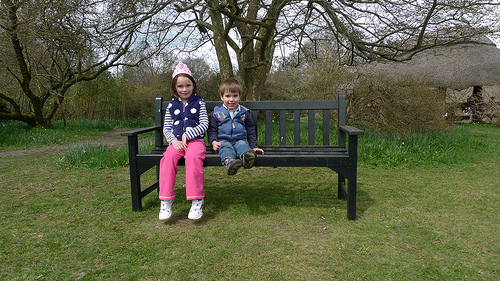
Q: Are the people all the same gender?
A: No, they are both male and female.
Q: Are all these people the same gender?
A: No, they are both male and female.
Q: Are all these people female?
A: No, they are both male and female.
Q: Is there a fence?
A: No, there are no fences.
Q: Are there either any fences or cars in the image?
A: No, there are no fences or cars.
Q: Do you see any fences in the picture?
A: No, there are no fences.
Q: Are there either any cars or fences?
A: No, there are no fences or cars.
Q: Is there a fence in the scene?
A: No, there are no fences.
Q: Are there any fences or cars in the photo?
A: No, there are no fences or cars.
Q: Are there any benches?
A: Yes, there is a bench.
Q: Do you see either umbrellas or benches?
A: Yes, there is a bench.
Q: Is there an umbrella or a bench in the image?
A: Yes, there is a bench.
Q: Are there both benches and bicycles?
A: No, there is a bench but no bikes.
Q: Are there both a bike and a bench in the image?
A: No, there is a bench but no bikes.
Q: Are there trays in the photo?
A: No, there are no trays.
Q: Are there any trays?
A: No, there are no trays.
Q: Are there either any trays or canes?
A: No, there are no trays or canes.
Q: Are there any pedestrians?
A: No, there are no pedestrians.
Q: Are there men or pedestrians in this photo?
A: No, there are no pedestrians or men.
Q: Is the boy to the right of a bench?
A: No, the boy is to the left of a bench.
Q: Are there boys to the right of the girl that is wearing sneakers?
A: Yes, there is a boy to the right of the girl.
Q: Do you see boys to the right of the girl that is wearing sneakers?
A: Yes, there is a boy to the right of the girl.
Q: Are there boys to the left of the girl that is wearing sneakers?
A: No, the boy is to the right of the girl.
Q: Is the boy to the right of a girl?
A: Yes, the boy is to the right of a girl.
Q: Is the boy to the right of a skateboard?
A: No, the boy is to the right of a girl.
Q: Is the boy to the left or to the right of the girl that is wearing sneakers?
A: The boy is to the right of the girl.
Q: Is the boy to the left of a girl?
A: No, the boy is to the right of a girl.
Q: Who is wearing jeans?
A: The boy is wearing jeans.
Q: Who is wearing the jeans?
A: The boy is wearing jeans.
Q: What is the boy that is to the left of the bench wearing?
A: The boy is wearing jeans.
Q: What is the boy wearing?
A: The boy is wearing jeans.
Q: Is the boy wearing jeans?
A: Yes, the boy is wearing jeans.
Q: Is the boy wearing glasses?
A: No, the boy is wearing jeans.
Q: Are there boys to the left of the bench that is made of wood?
A: Yes, there is a boy to the left of the bench.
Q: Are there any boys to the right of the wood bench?
A: No, the boy is to the left of the bench.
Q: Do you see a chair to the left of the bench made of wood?
A: No, there is a boy to the left of the bench.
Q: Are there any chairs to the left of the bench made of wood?
A: No, there is a boy to the left of the bench.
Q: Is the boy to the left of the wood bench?
A: Yes, the boy is to the left of the bench.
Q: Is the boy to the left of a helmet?
A: No, the boy is to the left of the bench.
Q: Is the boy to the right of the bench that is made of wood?
A: No, the boy is to the left of the bench.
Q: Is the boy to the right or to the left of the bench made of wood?
A: The boy is to the left of the bench.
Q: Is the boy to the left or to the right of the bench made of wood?
A: The boy is to the left of the bench.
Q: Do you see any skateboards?
A: No, there are no skateboards.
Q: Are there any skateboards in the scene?
A: No, there are no skateboards.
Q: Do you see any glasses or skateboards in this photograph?
A: No, there are no skateboards or glasses.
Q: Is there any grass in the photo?
A: Yes, there is grass.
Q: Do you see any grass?
A: Yes, there is grass.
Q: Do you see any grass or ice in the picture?
A: Yes, there is grass.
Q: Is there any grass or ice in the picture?
A: Yes, there is grass.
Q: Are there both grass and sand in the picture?
A: No, there is grass but no sand.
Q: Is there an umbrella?
A: No, there are no umbrellas.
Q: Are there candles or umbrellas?
A: No, there are no umbrellas or candles.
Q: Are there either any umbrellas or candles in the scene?
A: No, there are no umbrellas or candles.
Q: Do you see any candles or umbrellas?
A: No, there are no umbrellas or candles.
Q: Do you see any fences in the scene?
A: No, there are no fences.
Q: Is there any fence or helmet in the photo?
A: No, there are no fences or helmets.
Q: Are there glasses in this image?
A: No, there are no glasses.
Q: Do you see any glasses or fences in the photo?
A: No, there are no glasses or fences.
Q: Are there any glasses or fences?
A: No, there are no glasses or fences.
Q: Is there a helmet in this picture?
A: No, there are no helmets.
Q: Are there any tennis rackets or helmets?
A: No, there are no helmets or tennis rackets.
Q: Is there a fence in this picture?
A: No, there are no fences.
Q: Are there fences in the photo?
A: No, there are no fences.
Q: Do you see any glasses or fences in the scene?
A: No, there are no fences or glasses.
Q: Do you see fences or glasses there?
A: No, there are no fences or glasses.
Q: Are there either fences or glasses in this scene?
A: No, there are no fences or glasses.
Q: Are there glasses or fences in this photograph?
A: No, there are no fences or glasses.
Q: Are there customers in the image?
A: No, there are no customers.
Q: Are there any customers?
A: No, there are no customers.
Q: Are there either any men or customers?
A: No, there are no customers or men.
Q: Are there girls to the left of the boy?
A: Yes, there is a girl to the left of the boy.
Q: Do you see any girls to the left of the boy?
A: Yes, there is a girl to the left of the boy.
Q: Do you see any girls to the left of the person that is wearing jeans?
A: Yes, there is a girl to the left of the boy.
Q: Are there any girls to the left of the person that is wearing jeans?
A: Yes, there is a girl to the left of the boy.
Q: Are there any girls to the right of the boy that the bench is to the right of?
A: No, the girl is to the left of the boy.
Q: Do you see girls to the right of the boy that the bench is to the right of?
A: No, the girl is to the left of the boy.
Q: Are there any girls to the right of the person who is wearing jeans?
A: No, the girl is to the left of the boy.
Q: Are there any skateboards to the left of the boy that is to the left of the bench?
A: No, there is a girl to the left of the boy.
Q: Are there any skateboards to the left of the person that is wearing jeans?
A: No, there is a girl to the left of the boy.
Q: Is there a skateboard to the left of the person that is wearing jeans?
A: No, there is a girl to the left of the boy.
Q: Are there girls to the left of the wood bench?
A: Yes, there is a girl to the left of the bench.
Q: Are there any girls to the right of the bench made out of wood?
A: No, the girl is to the left of the bench.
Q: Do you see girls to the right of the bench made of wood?
A: No, the girl is to the left of the bench.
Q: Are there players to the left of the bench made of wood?
A: No, there is a girl to the left of the bench.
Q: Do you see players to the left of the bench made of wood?
A: No, there is a girl to the left of the bench.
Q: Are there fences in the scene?
A: No, there are no fences.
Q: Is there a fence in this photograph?
A: No, there are no fences.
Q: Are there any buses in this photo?
A: No, there are no buses.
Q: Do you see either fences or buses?
A: No, there are no buses or fences.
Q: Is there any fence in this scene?
A: No, there are no fences.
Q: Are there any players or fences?
A: No, there are no fences or players.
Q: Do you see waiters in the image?
A: No, there are no waiters.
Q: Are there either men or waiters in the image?
A: No, there are no waiters or men.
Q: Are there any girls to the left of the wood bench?
A: Yes, there is a girl to the left of the bench.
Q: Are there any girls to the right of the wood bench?
A: No, the girl is to the left of the bench.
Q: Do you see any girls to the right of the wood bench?
A: No, the girl is to the left of the bench.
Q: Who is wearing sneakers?
A: The girl is wearing sneakers.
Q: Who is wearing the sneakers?
A: The girl is wearing sneakers.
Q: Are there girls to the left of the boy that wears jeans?
A: Yes, there is a girl to the left of the boy.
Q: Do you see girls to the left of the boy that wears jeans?
A: Yes, there is a girl to the left of the boy.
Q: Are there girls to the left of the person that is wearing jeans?
A: Yes, there is a girl to the left of the boy.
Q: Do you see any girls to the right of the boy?
A: No, the girl is to the left of the boy.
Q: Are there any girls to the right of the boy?
A: No, the girl is to the left of the boy.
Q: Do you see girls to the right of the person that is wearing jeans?
A: No, the girl is to the left of the boy.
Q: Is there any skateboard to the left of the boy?
A: No, there is a girl to the left of the boy.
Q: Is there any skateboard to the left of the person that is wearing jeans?
A: No, there is a girl to the left of the boy.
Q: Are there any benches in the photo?
A: Yes, there is a bench.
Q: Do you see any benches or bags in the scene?
A: Yes, there is a bench.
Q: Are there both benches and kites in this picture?
A: No, there is a bench but no kites.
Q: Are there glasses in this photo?
A: No, there are no glasses.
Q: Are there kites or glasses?
A: No, there are no glasses or kites.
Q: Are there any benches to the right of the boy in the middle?
A: Yes, there is a bench to the right of the boy.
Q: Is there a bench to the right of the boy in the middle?
A: Yes, there is a bench to the right of the boy.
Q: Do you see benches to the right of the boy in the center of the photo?
A: Yes, there is a bench to the right of the boy.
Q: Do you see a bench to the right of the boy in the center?
A: Yes, there is a bench to the right of the boy.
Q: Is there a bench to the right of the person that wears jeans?
A: Yes, there is a bench to the right of the boy.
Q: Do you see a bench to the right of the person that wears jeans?
A: Yes, there is a bench to the right of the boy.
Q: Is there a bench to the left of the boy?
A: No, the bench is to the right of the boy.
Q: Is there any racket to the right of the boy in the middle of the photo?
A: No, there is a bench to the right of the boy.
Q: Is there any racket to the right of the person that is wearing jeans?
A: No, there is a bench to the right of the boy.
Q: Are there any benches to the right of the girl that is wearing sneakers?
A: Yes, there is a bench to the right of the girl.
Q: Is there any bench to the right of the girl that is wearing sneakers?
A: Yes, there is a bench to the right of the girl.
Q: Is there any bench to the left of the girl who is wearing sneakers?
A: No, the bench is to the right of the girl.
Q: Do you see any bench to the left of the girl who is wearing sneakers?
A: No, the bench is to the right of the girl.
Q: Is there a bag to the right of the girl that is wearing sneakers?
A: No, there is a bench to the right of the girl.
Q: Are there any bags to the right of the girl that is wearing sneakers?
A: No, there is a bench to the right of the girl.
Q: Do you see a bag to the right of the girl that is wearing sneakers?
A: No, there is a bench to the right of the girl.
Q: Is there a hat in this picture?
A: Yes, there is a hat.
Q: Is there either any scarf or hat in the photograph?
A: Yes, there is a hat.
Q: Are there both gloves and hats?
A: No, there is a hat but no gloves.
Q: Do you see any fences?
A: No, there are no fences.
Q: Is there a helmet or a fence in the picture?
A: No, there are no fences or helmets.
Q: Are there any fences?
A: No, there are no fences.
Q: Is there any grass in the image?
A: Yes, there is grass.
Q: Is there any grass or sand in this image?
A: Yes, there is grass.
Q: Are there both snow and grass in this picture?
A: No, there is grass but no snow.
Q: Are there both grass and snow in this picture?
A: No, there is grass but no snow.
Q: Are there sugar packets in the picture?
A: No, there are no sugar packets.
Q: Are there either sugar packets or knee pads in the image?
A: No, there are no sugar packets or knee pads.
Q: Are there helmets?
A: No, there are no helmets.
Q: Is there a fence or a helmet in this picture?
A: No, there are no helmets or fences.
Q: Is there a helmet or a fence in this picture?
A: No, there are no helmets or fences.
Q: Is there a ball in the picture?
A: No, there are no balls.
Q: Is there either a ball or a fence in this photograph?
A: No, there are no balls or fences.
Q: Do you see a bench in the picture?
A: Yes, there is a bench.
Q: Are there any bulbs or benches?
A: Yes, there is a bench.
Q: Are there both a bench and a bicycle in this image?
A: No, there is a bench but no bicycles.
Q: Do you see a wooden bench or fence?
A: Yes, there is a wood bench.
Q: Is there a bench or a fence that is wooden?
A: Yes, the bench is wooden.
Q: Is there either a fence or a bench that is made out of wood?
A: Yes, the bench is made of wood.